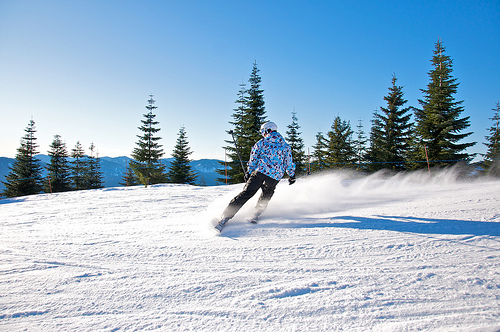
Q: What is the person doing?
A: Skiing.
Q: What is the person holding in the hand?
A: Ski pole.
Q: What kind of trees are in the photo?
A: Pine trees.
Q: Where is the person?
A: Snow covered hill.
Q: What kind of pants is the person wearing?
A: Black snow pants.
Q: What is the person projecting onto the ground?
A: Shadow.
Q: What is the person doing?
A: Skiing.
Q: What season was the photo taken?
A: Winter.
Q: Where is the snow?
A: On the ground.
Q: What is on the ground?
A: Snow.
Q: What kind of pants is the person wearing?
A: Ski pants.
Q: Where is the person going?
A: Downhill.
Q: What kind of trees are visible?
A: Pine trees.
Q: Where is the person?
A: On a mountain.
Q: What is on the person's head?
A: Helmet.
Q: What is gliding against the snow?
A: Person's leg.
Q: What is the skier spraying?
A: Snow.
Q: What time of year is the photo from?
A: Winter.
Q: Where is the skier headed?
A: Downhill.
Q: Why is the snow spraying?
A: The skier.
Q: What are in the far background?
A: Mountains.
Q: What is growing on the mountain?
A: Trees.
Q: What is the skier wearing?
A: Blue sweater.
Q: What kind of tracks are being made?
A: Ski tracks.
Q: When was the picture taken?
A: During the day.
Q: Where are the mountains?
A: Behind the trees.